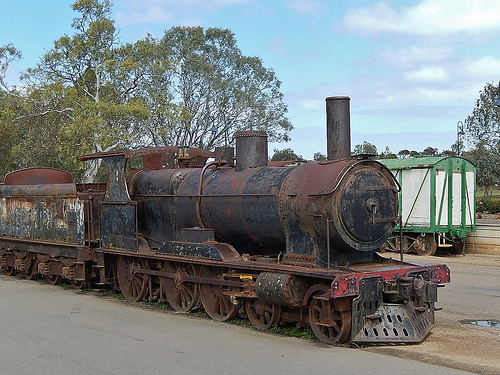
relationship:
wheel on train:
[241, 276, 287, 331] [102, 137, 438, 336]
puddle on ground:
[456, 310, 498, 331] [452, 340, 481, 375]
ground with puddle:
[452, 340, 481, 375] [456, 310, 498, 331]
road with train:
[33, 317, 207, 375] [0, 97, 441, 344]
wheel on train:
[241, 276, 287, 331] [0, 97, 441, 344]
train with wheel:
[0, 97, 441, 344] [241, 276, 287, 331]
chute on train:
[226, 112, 282, 182] [0, 97, 441, 344]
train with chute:
[0, 97, 441, 344] [226, 112, 282, 182]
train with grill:
[0, 97, 441, 344] [311, 279, 475, 353]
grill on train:
[311, 279, 475, 353] [0, 97, 441, 344]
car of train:
[5, 160, 93, 285] [0, 97, 441, 344]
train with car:
[0, 97, 441, 344] [5, 160, 93, 285]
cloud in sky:
[421, 99, 451, 102] [418, 107, 454, 137]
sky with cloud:
[418, 107, 454, 137] [421, 99, 451, 102]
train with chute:
[0, 97, 441, 344] [227, 126, 270, 172]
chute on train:
[227, 126, 270, 172] [0, 97, 441, 344]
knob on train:
[356, 194, 386, 231] [0, 97, 441, 344]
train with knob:
[0, 97, 441, 344] [356, 194, 386, 231]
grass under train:
[76, 297, 377, 353] [0, 97, 441, 344]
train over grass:
[0, 97, 441, 344] [76, 297, 377, 353]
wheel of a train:
[214, 269, 288, 353] [206, 151, 441, 351]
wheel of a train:
[160, 264, 197, 314] [256, 164, 433, 375]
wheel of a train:
[169, 264, 211, 338] [230, 149, 425, 295]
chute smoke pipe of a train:
[227, 126, 270, 172] [265, 195, 431, 333]